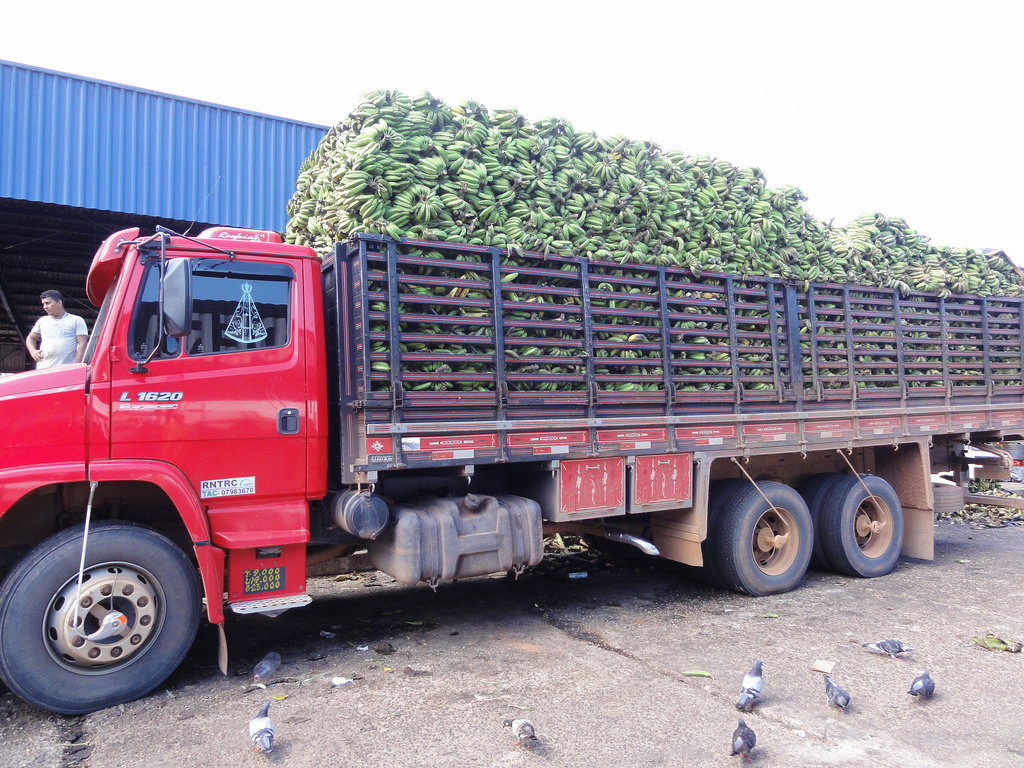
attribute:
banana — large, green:
[264, 84, 1021, 407]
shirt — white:
[31, 307, 88, 371]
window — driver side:
[133, 256, 292, 365]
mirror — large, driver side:
[141, 245, 202, 359]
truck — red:
[5, 213, 1023, 713]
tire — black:
[0, 520, 198, 723]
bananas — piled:
[285, 86, 1022, 415]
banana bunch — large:
[405, 148, 451, 192]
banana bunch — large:
[348, 185, 390, 227]